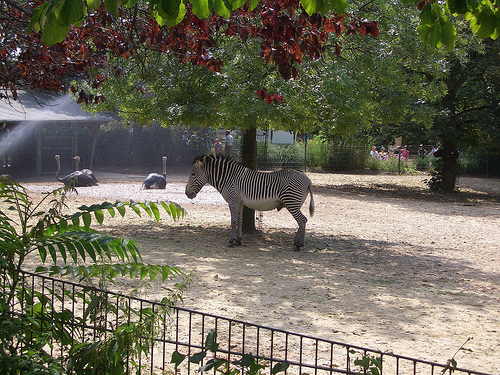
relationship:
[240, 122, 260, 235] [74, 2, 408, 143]
tree has leaves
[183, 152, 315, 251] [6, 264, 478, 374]
zebra behind fence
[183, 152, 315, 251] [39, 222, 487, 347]
zebra in shadow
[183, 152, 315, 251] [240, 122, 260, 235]
zebra under tree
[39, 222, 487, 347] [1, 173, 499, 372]
shadow on ground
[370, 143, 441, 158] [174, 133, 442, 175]
people are behind fence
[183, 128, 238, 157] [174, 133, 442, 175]
people are behind fence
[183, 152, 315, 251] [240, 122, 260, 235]
zebra breath tree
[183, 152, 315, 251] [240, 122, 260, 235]
zebra beneath tree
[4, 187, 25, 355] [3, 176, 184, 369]
bush has leaves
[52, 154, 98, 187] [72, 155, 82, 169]
ostriche sitting next to ostriche